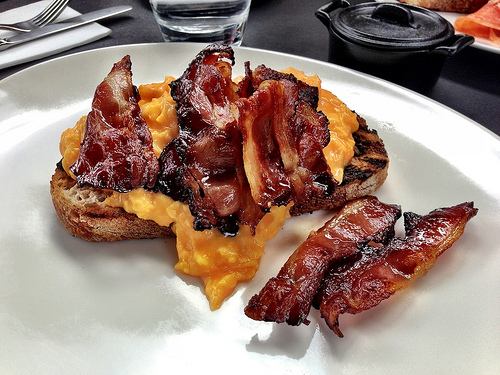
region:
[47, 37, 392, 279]
open-face bacon and cheese sandwich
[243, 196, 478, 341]
two slices of bacon on plate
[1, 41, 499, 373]
white ceramic plate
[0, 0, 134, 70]
eating utensils on napkin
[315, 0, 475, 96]
small black pot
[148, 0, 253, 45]
clear drinking glass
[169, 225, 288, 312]
melted cheese dripping onto plate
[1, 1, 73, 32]
fork on napkin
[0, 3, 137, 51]
butter knife on white napkin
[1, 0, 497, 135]
dark gray table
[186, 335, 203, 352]
the plate is white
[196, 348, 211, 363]
the plate is white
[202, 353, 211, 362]
the plate is white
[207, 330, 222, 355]
the plate is white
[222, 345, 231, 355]
the plate is white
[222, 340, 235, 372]
the plate is white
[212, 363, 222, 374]
the plate is white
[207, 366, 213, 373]
the plate is white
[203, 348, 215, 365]
the plate is white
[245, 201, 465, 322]
a side of crispy bacon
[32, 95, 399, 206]
bacon egg and cheese on toast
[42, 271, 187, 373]
a white plate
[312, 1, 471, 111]
a small asian rice dish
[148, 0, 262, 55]
a glass of water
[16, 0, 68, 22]
a silver fork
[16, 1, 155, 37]
a silver butter knife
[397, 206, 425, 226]
burn marks on crispy bacon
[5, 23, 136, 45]
a white folded knapkin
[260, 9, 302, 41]
a solid black counter top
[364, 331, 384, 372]
the plate is white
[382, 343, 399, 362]
the plate is white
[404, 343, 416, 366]
the plate is white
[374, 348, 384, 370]
the plate is white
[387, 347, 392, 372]
the plate is white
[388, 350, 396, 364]
the plate is white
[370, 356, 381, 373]
the plate is white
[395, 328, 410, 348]
the plate is white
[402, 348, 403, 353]
the plate is white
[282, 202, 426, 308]
piece of bacon on white plate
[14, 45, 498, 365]
white plate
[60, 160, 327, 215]
toasted piece of bread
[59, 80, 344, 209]
cheese and bacon on bread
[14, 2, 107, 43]
silver fork on napkin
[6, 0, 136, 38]
silver knife on napkin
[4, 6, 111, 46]
white napkin on black table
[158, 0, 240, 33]
glass of water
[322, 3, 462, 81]
small black pot next to plate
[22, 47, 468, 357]
meal on white plate